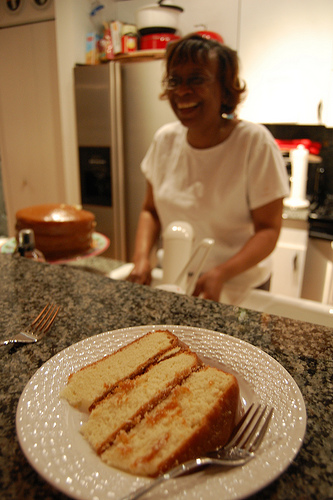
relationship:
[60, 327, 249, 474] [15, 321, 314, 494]
food on plate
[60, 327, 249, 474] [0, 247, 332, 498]
food on table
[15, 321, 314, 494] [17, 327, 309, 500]
plate has design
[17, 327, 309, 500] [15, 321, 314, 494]
design on plate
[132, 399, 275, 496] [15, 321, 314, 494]
fork on plate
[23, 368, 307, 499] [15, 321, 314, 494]
light on plate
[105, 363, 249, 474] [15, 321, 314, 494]
food on plate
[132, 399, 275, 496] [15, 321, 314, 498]
fork on plate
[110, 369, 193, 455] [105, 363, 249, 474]
crumbs on food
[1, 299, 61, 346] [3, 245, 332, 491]
fork on counter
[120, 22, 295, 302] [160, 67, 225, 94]
woman has eyeglasses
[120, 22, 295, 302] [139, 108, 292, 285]
woman has shirt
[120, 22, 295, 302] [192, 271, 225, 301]
woman has hand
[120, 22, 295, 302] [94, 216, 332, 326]
woman at kitchen sink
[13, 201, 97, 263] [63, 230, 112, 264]
cake on cake plate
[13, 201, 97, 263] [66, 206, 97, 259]
cake with piece missing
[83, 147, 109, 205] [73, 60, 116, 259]
water dispenser in door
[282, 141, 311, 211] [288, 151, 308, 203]
rack for paper towel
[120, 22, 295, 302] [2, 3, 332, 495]
woman in kitchen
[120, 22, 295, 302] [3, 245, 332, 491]
woman behind counter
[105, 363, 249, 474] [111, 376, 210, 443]
food with bits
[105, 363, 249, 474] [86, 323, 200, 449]
food with icing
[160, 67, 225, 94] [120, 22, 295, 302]
eyeglasses on woman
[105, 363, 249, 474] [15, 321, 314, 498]
food on plate